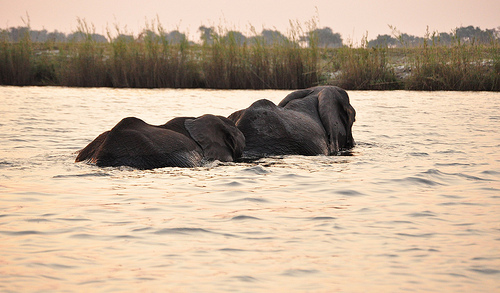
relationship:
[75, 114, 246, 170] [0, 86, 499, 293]
elephant in water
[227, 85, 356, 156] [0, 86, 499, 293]
elephant in water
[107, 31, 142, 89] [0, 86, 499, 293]
plant next to water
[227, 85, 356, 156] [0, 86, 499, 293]
elephant submerged in water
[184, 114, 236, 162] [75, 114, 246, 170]
ear of elephant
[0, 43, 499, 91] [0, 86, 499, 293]
field next to water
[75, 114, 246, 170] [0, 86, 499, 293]
elephant bathing in water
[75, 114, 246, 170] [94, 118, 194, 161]
elephant has spine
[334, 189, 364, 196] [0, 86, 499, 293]
wave in water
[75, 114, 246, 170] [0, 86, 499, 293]
elephant wading through water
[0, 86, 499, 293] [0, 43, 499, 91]
water and field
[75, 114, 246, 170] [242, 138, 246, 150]
elephant has eye